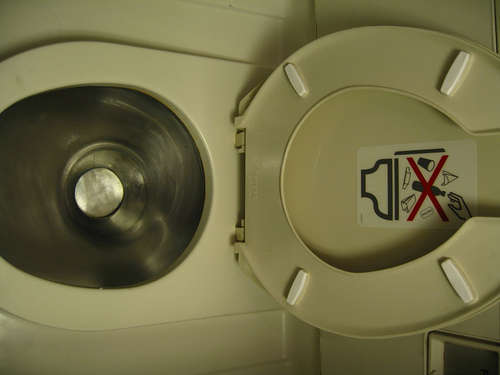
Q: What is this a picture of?
A: An open toilet lid.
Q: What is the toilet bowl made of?
A: Plastic and metal.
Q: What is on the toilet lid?
A: A sign.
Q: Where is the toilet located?
A: In an airplane.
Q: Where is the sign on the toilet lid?
A: Underneath.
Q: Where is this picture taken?
A: In a bathroom.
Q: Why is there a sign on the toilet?
A: Preventing hazards to toilet.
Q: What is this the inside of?
A: The toilet.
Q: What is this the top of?
A: The toilet seat.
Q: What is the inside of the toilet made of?
A: Stainless steel.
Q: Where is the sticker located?
A: Inside of the toilet.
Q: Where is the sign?
A: On the toilet lid.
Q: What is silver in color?
A: The toilet.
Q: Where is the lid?
A: Up in the air.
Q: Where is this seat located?
A: In the plane.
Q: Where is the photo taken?
A: Inside a bathroom.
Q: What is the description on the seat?
A: White.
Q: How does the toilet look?
A: Its clean.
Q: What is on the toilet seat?
A: Bottle and cups.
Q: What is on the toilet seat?
A: Instructions.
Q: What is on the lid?
A: Under side of toilet.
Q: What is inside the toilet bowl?
A: Metal.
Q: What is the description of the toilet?
A: Vanilla colored.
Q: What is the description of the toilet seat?
A: Tan Colored.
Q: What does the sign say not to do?
A: Throw trash down the toilet.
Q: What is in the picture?
A: A toilet.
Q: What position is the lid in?
A: The lid is up.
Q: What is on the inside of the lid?
A: A warning sticker.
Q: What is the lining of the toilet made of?
A: Metal.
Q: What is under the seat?
A: Four spacers.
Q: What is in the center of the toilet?
A: A drain hole.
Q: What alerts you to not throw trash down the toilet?
A: The sign.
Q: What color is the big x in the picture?
A: Red.